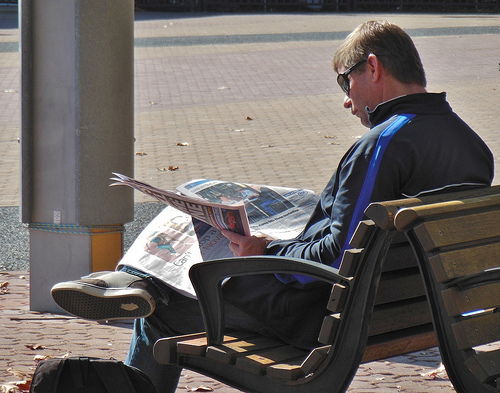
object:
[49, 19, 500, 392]
man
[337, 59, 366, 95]
sunglasses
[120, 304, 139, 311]
chewing gum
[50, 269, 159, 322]
sole of shoe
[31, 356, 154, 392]
bag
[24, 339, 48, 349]
leaves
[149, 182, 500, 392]
bench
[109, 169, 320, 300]
newspaper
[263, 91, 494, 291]
windbreaker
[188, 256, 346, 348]
armrest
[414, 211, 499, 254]
slat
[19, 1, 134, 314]
pillar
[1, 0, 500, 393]
ground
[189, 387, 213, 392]
leaf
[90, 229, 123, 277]
panel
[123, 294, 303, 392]
legs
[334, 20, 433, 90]
hair